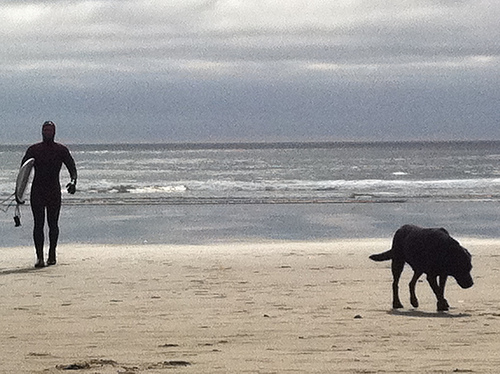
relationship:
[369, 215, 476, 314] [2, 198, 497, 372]
dog walking on sand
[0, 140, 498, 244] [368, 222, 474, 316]
water behind dog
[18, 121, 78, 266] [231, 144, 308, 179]
man out of water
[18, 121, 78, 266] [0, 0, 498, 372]
man walking on beach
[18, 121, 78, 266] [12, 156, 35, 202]
man has surf board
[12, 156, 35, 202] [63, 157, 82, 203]
surf board under arm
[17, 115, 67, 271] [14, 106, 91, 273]
man wears suit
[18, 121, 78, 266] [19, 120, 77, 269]
man wears suit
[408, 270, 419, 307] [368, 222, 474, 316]
leg of dog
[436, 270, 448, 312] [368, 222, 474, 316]
leg of dog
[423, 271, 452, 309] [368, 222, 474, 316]
leg of dog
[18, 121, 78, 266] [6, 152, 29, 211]
man carrying surfboard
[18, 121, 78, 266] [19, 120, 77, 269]
man wearing suit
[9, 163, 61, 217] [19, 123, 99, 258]
surf board under man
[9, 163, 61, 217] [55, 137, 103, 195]
surf board under arm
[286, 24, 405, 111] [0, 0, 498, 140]
clouds in sky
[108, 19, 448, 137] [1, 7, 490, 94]
sky full of clouds